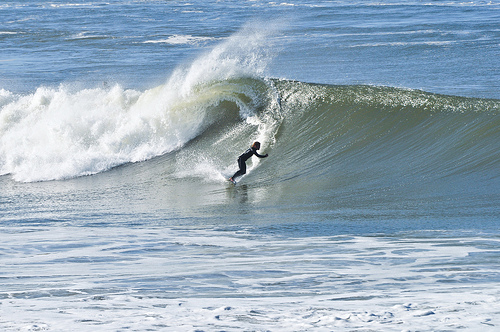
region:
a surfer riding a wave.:
[218, 111, 295, 201]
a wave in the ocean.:
[0, 84, 497, 206]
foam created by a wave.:
[0, 26, 307, 190]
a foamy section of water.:
[2, 276, 492, 329]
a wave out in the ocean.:
[130, 15, 427, 62]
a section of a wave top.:
[241, 55, 476, 135]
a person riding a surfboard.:
[224, 113, 271, 203]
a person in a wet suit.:
[210, 133, 271, 188]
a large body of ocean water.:
[0, 0, 499, 94]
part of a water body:
[361, 214, 378, 232]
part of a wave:
[389, 180, 409, 204]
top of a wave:
[373, 95, 388, 103]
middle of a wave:
[363, 132, 385, 133]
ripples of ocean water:
[160, 201, 171, 213]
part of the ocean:
[291, 254, 303, 262]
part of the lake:
[265, 267, 289, 302]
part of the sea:
[161, 277, 182, 299]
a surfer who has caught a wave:
[211, 130, 278, 200]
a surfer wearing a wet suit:
[215, 128, 278, 198]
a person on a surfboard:
[210, 127, 284, 199]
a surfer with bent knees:
[214, 125, 274, 190]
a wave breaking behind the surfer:
[0, 42, 287, 134]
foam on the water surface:
[201, 229, 421, 308]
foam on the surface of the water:
[141, 226, 383, 298]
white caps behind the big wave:
[0, 17, 204, 52]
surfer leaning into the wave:
[216, 130, 273, 193]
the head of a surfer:
[252, 137, 261, 151]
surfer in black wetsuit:
[216, 134, 295, 211]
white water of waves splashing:
[203, 30, 281, 76]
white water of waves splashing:
[116, 91, 151, 131]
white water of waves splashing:
[39, 105, 72, 134]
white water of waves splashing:
[26, 88, 53, 108]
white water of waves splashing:
[205, 293, 241, 318]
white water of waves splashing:
[374, 76, 404, 106]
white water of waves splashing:
[253, 119, 269, 136]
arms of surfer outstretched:
[254, 152, 268, 161]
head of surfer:
[249, 137, 262, 152]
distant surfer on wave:
[229, 137, 274, 193]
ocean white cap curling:
[2, 45, 287, 202]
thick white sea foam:
[15, 280, 487, 330]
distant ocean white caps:
[137, 22, 477, 54]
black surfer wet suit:
[227, 137, 277, 193]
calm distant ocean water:
[19, 7, 477, 89]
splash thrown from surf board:
[173, 145, 243, 194]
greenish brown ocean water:
[265, 22, 498, 232]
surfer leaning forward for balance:
[215, 125, 279, 191]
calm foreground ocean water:
[15, 216, 492, 323]